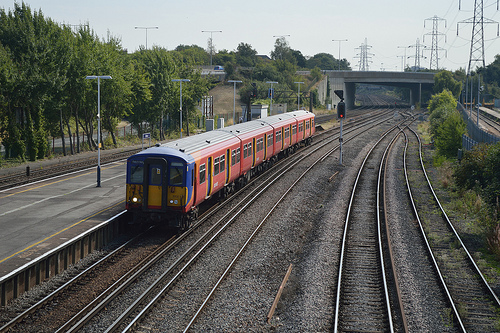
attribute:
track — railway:
[23, 239, 171, 331]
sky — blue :
[5, 2, 497, 70]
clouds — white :
[429, 14, 495, 64]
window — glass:
[197, 161, 209, 183]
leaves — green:
[13, 26, 57, 88]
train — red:
[116, 97, 324, 233]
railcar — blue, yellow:
[128, 127, 240, 235]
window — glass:
[196, 159, 207, 187]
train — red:
[239, 113, 275, 164]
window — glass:
[213, 158, 219, 173]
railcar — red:
[126, 107, 315, 232]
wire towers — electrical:
[401, 14, 462, 72]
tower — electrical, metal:
[414, 12, 455, 78]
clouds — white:
[314, 9, 419, 61]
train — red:
[126, 108, 316, 228]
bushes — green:
[423, 83, 473, 170]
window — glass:
[217, 152, 230, 171]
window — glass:
[254, 131, 270, 163]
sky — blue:
[4, 1, 484, 87]